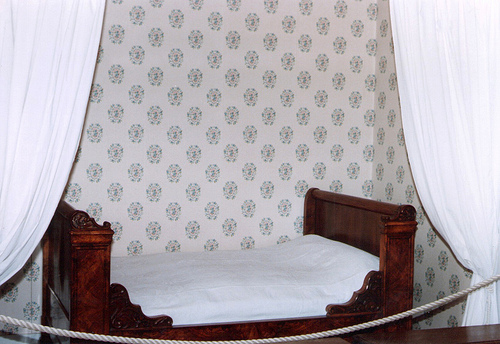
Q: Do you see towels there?
A: No, there are no towels.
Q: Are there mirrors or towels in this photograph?
A: No, there are no towels or mirrors.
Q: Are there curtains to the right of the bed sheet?
A: Yes, there is a curtain to the right of the bed sheet.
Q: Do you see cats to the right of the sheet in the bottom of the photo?
A: No, there is a curtain to the right of the bed sheet.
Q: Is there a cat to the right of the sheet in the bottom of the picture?
A: No, there is a curtain to the right of the bed sheet.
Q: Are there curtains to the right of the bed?
A: Yes, there is a curtain to the right of the bed.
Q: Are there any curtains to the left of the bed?
A: No, the curtain is to the right of the bed.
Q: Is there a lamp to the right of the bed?
A: No, there is a curtain to the right of the bed.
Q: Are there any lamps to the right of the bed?
A: No, there is a curtain to the right of the bed.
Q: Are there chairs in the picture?
A: No, there are no chairs.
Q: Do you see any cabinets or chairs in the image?
A: No, there are no chairs or cabinets.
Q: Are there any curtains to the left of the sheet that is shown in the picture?
A: Yes, there is a curtain to the left of the sheet.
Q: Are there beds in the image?
A: Yes, there is a bed.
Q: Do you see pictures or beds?
A: Yes, there is a bed.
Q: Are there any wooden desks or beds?
A: Yes, there is a wood bed.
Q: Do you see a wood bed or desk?
A: Yes, there is a wood bed.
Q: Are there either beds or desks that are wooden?
A: Yes, the bed is wooden.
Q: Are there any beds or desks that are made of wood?
A: Yes, the bed is made of wood.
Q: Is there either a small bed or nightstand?
A: Yes, there is a small bed.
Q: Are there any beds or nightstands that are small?
A: Yes, the bed is small.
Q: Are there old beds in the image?
A: Yes, there is an old bed.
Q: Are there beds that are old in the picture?
A: Yes, there is an old bed.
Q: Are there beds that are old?
A: Yes, there is a bed that is old.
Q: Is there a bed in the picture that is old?
A: Yes, there is a bed that is old.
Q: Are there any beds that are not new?
A: Yes, there is a old bed.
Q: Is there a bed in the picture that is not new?
A: Yes, there is a old bed.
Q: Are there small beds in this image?
A: Yes, there is a small bed.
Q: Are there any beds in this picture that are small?
A: Yes, there is a small bed.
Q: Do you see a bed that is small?
A: Yes, there is a bed that is small.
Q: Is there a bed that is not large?
A: Yes, there is a small bed.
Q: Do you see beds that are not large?
A: Yes, there is a small bed.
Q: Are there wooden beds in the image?
A: Yes, there is a wood bed.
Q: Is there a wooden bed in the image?
A: Yes, there is a wood bed.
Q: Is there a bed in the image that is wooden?
A: Yes, there is a bed that is wooden.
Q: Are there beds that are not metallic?
A: Yes, there is a wooden bed.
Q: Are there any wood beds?
A: Yes, there is a bed that is made of wood.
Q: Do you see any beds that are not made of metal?
A: Yes, there is a bed that is made of wood.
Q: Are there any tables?
A: No, there are no tables.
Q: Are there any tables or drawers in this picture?
A: No, there are no tables or drawers.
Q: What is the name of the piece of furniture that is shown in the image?
A: The piece of furniture is a bed.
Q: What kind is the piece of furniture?
A: The piece of furniture is a bed.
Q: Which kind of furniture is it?
A: The piece of furniture is a bed.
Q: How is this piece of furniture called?
A: This is a bed.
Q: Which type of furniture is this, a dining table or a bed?
A: This is a bed.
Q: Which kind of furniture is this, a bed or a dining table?
A: This is a bed.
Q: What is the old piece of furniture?
A: The piece of furniture is a bed.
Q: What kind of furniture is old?
A: The furniture is a bed.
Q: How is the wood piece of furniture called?
A: The piece of furniture is a bed.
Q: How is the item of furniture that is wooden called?
A: The piece of furniture is a bed.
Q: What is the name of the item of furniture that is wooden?
A: The piece of furniture is a bed.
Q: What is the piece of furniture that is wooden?
A: The piece of furniture is a bed.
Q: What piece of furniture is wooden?
A: The piece of furniture is a bed.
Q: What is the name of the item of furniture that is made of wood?
A: The piece of furniture is a bed.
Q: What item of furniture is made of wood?
A: The piece of furniture is a bed.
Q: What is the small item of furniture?
A: The piece of furniture is a bed.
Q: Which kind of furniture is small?
A: The furniture is a bed.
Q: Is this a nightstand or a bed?
A: This is a bed.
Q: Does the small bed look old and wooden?
A: Yes, the bed is old and wooden.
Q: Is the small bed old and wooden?
A: Yes, the bed is old and wooden.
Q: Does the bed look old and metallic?
A: No, the bed is old but wooden.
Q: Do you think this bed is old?
A: Yes, the bed is old.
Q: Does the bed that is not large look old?
A: Yes, the bed is old.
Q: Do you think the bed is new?
A: No, the bed is old.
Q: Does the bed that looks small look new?
A: No, the bed is old.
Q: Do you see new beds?
A: No, there is a bed but it is old.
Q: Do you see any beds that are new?
A: No, there is a bed but it is old.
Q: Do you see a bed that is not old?
A: No, there is a bed but it is old.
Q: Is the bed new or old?
A: The bed is old.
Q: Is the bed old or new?
A: The bed is old.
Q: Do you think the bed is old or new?
A: The bed is old.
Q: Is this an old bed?
A: Yes, this is an old bed.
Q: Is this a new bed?
A: No, this is an old bed.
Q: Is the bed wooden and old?
A: Yes, the bed is wooden and old.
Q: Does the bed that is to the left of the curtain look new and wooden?
A: No, the bed is wooden but old.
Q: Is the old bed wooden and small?
A: Yes, the bed is wooden and small.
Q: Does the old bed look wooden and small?
A: Yes, the bed is wooden and small.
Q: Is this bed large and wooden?
A: No, the bed is wooden but small.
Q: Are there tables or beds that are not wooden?
A: No, there is a bed but it is wooden.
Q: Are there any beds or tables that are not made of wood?
A: No, there is a bed but it is made of wood.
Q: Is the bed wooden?
A: Yes, the bed is wooden.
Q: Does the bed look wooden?
A: Yes, the bed is wooden.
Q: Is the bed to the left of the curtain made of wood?
A: Yes, the bed is made of wood.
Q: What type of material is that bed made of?
A: The bed is made of wood.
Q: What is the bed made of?
A: The bed is made of wood.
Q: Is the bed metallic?
A: No, the bed is wooden.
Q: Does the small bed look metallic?
A: No, the bed is wooden.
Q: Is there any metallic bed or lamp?
A: No, there is a bed but it is wooden.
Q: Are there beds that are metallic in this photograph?
A: No, there is a bed but it is wooden.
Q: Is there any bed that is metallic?
A: No, there is a bed but it is wooden.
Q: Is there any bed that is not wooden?
A: No, there is a bed but it is wooden.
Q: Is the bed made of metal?
A: No, the bed is made of wood.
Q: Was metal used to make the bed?
A: No, the bed is made of wood.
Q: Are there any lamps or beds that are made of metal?
A: No, there is a bed but it is made of wood.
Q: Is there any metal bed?
A: No, there is a bed but it is made of wood.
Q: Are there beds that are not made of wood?
A: No, there is a bed but it is made of wood.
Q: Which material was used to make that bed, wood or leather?
A: The bed is made of wood.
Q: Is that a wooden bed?
A: Yes, that is a wooden bed.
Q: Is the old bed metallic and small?
A: No, the bed is small but wooden.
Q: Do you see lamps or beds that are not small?
A: No, there is a bed but it is small.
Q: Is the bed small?
A: Yes, the bed is small.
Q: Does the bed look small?
A: Yes, the bed is small.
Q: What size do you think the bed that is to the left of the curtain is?
A: The bed is small.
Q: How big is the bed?
A: The bed is small.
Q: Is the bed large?
A: No, the bed is small.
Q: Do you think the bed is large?
A: No, the bed is small.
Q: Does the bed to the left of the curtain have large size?
A: No, the bed is small.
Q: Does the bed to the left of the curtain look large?
A: No, the bed is small.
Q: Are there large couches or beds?
A: No, there is a bed but it is small.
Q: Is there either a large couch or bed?
A: No, there is a bed but it is small.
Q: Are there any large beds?
A: No, there is a bed but it is small.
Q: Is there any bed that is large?
A: No, there is a bed but it is small.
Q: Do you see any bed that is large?
A: No, there is a bed but it is small.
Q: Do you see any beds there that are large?
A: No, there is a bed but it is small.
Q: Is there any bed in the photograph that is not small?
A: No, there is a bed but it is small.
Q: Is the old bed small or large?
A: The bed is small.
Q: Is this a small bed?
A: Yes, this is a small bed.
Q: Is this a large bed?
A: No, this is a small bed.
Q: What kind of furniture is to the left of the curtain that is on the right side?
A: The piece of furniture is a bed.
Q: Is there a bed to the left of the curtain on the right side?
A: Yes, there is a bed to the left of the curtain.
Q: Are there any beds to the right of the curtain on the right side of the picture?
A: No, the bed is to the left of the curtain.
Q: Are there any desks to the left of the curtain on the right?
A: No, there is a bed to the left of the curtain.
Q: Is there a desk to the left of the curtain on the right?
A: No, there is a bed to the left of the curtain.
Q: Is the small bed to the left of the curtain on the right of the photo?
A: Yes, the bed is to the left of the curtain.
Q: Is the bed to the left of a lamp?
A: No, the bed is to the left of the curtain.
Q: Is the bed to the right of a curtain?
A: No, the bed is to the left of a curtain.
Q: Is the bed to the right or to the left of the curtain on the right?
A: The bed is to the left of the curtain.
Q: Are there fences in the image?
A: No, there are no fences.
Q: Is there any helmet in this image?
A: No, there are no helmets.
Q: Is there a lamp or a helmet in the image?
A: No, there are no helmets or lamps.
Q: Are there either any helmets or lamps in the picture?
A: No, there are no helmets or lamps.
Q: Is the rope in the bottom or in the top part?
A: The rope is in the bottom of the image.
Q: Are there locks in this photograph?
A: No, there are no locks.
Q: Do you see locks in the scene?
A: No, there are no locks.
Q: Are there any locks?
A: No, there are no locks.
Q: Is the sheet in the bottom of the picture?
A: Yes, the sheet is in the bottom of the image.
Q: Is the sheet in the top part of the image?
A: No, the sheet is in the bottom of the image.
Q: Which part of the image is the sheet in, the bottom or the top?
A: The sheet is in the bottom of the image.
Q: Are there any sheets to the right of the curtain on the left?
A: Yes, there is a sheet to the right of the curtain.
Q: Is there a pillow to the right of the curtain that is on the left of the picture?
A: No, there is a sheet to the right of the curtain.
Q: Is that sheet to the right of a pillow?
A: No, the sheet is to the right of a curtain.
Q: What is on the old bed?
A: The bed sheet is on the bed.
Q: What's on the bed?
A: The bed sheet is on the bed.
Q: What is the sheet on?
A: The sheet is on the bed.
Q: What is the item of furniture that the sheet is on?
A: The piece of furniture is a bed.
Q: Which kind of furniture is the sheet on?
A: The sheet is on the bed.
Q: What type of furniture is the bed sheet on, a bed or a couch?
A: The bed sheet is on a bed.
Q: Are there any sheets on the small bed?
A: Yes, there is a sheet on the bed.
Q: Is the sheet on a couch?
A: No, the sheet is on a bed.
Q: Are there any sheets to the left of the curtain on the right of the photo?
A: Yes, there is a sheet to the left of the curtain.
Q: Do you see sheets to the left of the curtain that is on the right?
A: Yes, there is a sheet to the left of the curtain.